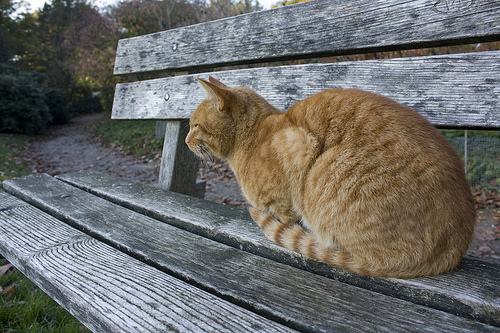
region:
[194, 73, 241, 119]
Cat has tan ear.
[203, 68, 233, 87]
Cat has tan ear.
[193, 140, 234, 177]
Cat has white whiskers.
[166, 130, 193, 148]
Cat has pink nose.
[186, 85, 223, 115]
Cat has tan face.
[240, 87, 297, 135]
Cat has tan neck.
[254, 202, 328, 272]
Cat has stripes on tail.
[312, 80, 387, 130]
Cat has stripes on back.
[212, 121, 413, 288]
Cat is sitting on wood bench.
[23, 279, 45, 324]
Green grass under wood bench.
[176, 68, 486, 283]
orange and yellow striped cat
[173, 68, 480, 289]
striped tabby sitting on bench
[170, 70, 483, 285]
tabby cat facing left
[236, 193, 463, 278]
striped tail curled around cat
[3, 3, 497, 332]
gray wooden park bench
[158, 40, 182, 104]
bolts holding bench together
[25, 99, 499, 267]
walking path behind bench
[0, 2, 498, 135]
grove of trees in distance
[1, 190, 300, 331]
wood grain in slat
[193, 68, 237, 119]
cat ears pointed left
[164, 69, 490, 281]
orange tabby cat sitting on gray wooden bench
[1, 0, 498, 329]
gray park bench made from slats of aged wood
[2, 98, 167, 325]
green grass growing on other side of grey path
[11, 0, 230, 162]
lush trees in background growing in park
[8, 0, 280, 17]
clear sunny sky above trees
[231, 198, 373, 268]
striped tail of cat curtled unde cat's body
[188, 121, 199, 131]
eyes of cat almost closed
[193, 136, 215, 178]
white whiskers growing on side of cat's jowels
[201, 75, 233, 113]
two pointed ears of cat standing alert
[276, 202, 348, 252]
white underbelly of predominately orange cat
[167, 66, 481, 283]
The cat has golden fur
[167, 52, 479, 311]
The cat is sitting on the bench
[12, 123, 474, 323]
The bench is made of wood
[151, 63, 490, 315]
The cat sits on the wooden bench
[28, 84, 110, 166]
A dirt path is alongside the bench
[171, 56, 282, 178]
The cat is looking forward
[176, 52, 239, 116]
The cat's ears are pointed up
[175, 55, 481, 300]
The cat is curled up into a ball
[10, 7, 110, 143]
Trees and bushes are in the park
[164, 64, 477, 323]
The golden cat sits on the wooden bench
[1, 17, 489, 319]
a wooden bench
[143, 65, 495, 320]
a cat lying on a bench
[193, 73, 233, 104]
the ears of a cat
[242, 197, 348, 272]
the tail of a cat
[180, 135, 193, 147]
the nose of a cat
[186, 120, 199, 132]
the eye of a cat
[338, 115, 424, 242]
the fur of a cat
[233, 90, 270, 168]
the neck of a cat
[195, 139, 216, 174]
the whiskers of a cat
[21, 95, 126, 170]
a trail through the woods